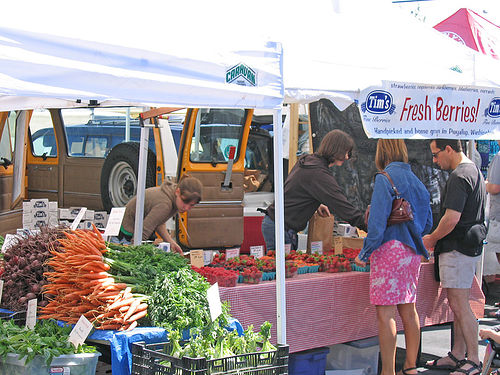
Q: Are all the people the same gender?
A: No, they are both male and female.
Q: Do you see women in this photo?
A: Yes, there is a woman.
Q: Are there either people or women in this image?
A: Yes, there is a woman.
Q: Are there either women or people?
A: Yes, there is a woman.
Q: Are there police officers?
A: No, there are no police officers.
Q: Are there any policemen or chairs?
A: No, there are no policemen or chairs.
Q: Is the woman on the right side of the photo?
A: Yes, the woman is on the right of the image.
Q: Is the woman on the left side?
A: No, the woman is on the right of the image.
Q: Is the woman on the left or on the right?
A: The woman is on the right of the image.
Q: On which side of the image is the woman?
A: The woman is on the right of the image.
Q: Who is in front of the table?
A: The woman is in front of the table.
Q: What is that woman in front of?
A: The woman is in front of the table.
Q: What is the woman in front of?
A: The woman is in front of the table.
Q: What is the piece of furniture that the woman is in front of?
A: The piece of furniture is a table.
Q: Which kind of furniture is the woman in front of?
A: The woman is in front of the table.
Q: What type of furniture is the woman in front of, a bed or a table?
A: The woman is in front of a table.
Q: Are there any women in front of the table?
A: Yes, there is a woman in front of the table.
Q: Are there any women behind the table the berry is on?
A: No, the woman is in front of the table.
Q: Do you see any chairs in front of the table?
A: No, there is a woman in front of the table.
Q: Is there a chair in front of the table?
A: No, there is a woman in front of the table.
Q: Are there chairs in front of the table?
A: No, there is a woman in front of the table.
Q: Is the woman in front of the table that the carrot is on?
A: Yes, the woman is in front of the table.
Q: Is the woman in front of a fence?
A: No, the woman is in front of the table.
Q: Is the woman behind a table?
A: No, the woman is in front of a table.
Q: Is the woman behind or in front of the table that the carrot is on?
A: The woman is in front of the table.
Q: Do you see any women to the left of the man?
A: Yes, there is a woman to the left of the man.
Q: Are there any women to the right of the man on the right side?
A: No, the woman is to the left of the man.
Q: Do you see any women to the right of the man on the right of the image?
A: No, the woman is to the left of the man.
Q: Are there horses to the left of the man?
A: No, there is a woman to the left of the man.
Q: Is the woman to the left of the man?
A: Yes, the woman is to the left of the man.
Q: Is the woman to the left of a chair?
A: No, the woman is to the left of the man.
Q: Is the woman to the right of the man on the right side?
A: No, the woman is to the left of the man.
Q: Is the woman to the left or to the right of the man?
A: The woman is to the left of the man.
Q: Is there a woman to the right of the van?
A: Yes, there is a woman to the right of the van.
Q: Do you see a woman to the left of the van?
A: No, the woman is to the right of the van.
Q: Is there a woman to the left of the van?
A: No, the woman is to the right of the van.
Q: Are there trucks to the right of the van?
A: No, there is a woman to the right of the van.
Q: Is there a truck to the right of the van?
A: No, there is a woman to the right of the van.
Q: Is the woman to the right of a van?
A: Yes, the woman is to the right of a van.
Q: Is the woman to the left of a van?
A: No, the woman is to the right of a van.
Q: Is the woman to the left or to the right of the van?
A: The woman is to the right of the van.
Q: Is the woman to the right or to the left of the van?
A: The woman is to the right of the van.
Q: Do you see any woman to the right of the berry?
A: Yes, there is a woman to the right of the berry.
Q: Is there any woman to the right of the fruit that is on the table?
A: Yes, there is a woman to the right of the berry.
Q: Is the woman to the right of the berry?
A: Yes, the woman is to the right of the berry.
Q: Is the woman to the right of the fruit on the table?
A: Yes, the woman is to the right of the berry.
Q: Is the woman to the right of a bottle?
A: No, the woman is to the right of the berry.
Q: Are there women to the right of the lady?
A: Yes, there is a woman to the right of the lady.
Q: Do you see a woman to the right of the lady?
A: Yes, there is a woman to the right of the lady.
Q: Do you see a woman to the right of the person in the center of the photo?
A: Yes, there is a woman to the right of the lady.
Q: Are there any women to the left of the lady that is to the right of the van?
A: No, the woman is to the right of the lady.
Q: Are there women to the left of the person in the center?
A: No, the woman is to the right of the lady.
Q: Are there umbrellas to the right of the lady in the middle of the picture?
A: No, there is a woman to the right of the lady.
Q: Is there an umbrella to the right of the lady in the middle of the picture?
A: No, there is a woman to the right of the lady.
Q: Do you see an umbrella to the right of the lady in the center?
A: No, there is a woman to the right of the lady.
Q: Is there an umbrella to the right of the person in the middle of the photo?
A: No, there is a woman to the right of the lady.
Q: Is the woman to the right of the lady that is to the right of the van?
A: Yes, the woman is to the right of the lady.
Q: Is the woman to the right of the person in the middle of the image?
A: Yes, the woman is to the right of the lady.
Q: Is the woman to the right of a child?
A: No, the woman is to the right of the lady.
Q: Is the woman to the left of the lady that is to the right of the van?
A: No, the woman is to the right of the lady.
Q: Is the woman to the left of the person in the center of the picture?
A: No, the woman is to the right of the lady.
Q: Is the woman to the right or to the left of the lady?
A: The woman is to the right of the lady.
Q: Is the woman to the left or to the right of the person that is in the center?
A: The woman is to the right of the lady.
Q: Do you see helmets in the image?
A: No, there are no helmets.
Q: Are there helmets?
A: No, there are no helmets.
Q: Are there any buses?
A: No, there are no buses.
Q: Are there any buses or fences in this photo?
A: No, there are no buses or fences.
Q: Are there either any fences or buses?
A: No, there are no buses or fences.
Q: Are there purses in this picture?
A: Yes, there is a purse.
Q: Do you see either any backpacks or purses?
A: Yes, there is a purse.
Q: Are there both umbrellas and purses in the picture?
A: No, there is a purse but no umbrellas.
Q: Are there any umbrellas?
A: No, there are no umbrellas.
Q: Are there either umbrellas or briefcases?
A: No, there are no umbrellas or briefcases.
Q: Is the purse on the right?
A: Yes, the purse is on the right of the image.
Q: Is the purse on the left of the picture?
A: No, the purse is on the right of the image.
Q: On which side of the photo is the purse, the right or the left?
A: The purse is on the right of the image.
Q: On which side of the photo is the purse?
A: The purse is on the right of the image.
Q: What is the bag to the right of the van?
A: The bag is a purse.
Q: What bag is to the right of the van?
A: The bag is a purse.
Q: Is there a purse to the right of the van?
A: Yes, there is a purse to the right of the van.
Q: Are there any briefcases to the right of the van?
A: No, there is a purse to the right of the van.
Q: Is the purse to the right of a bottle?
A: No, the purse is to the right of the van.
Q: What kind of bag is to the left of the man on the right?
A: The bag is a purse.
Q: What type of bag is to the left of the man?
A: The bag is a purse.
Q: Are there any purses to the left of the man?
A: Yes, there is a purse to the left of the man.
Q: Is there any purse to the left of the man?
A: Yes, there is a purse to the left of the man.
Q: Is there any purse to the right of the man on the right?
A: No, the purse is to the left of the man.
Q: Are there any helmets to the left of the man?
A: No, there is a purse to the left of the man.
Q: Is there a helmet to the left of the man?
A: No, there is a purse to the left of the man.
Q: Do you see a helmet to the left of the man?
A: No, there is a purse to the left of the man.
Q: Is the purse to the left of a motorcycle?
A: No, the purse is to the left of the man.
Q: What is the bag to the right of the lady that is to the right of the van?
A: The bag is a purse.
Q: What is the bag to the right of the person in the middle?
A: The bag is a purse.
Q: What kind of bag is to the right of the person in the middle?
A: The bag is a purse.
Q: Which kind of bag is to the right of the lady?
A: The bag is a purse.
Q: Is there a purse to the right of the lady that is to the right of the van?
A: Yes, there is a purse to the right of the lady.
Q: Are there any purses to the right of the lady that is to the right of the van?
A: Yes, there is a purse to the right of the lady.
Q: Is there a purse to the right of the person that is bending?
A: Yes, there is a purse to the right of the lady.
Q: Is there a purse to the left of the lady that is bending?
A: No, the purse is to the right of the lady.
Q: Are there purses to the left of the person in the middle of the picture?
A: No, the purse is to the right of the lady.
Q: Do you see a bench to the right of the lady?
A: No, there is a purse to the right of the lady.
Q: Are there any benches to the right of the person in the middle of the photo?
A: No, there is a purse to the right of the lady.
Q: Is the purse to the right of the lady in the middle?
A: Yes, the purse is to the right of the lady.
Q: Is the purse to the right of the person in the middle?
A: Yes, the purse is to the right of the lady.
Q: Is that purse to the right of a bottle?
A: No, the purse is to the right of the lady.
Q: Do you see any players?
A: No, there are no players.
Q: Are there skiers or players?
A: No, there are no players or skiers.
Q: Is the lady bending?
A: Yes, the lady is bending.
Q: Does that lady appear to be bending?
A: Yes, the lady is bending.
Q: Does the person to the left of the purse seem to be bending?
A: Yes, the lady is bending.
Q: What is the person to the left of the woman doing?
A: The lady is bending.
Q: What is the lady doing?
A: The lady is bending.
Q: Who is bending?
A: The lady is bending.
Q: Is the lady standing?
A: No, the lady is bending.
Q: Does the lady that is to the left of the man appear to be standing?
A: No, the lady is bending.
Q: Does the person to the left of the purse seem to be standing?
A: No, the lady is bending.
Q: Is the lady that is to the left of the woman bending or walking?
A: The lady is bending.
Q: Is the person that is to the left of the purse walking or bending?
A: The lady is bending.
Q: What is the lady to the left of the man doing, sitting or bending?
A: The lady is bending.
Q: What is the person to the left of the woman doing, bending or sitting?
A: The lady is bending.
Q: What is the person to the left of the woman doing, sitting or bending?
A: The lady is bending.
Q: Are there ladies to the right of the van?
A: Yes, there is a lady to the right of the van.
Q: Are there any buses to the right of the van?
A: No, there is a lady to the right of the van.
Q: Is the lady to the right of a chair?
A: No, the lady is to the right of the van.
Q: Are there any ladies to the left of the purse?
A: Yes, there is a lady to the left of the purse.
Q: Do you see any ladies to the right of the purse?
A: No, the lady is to the left of the purse.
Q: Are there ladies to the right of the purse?
A: No, the lady is to the left of the purse.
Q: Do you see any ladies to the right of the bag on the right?
A: No, the lady is to the left of the purse.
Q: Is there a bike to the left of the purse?
A: No, there is a lady to the left of the purse.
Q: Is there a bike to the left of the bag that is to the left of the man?
A: No, there is a lady to the left of the purse.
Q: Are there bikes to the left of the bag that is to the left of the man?
A: No, there is a lady to the left of the purse.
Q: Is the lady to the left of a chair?
A: No, the lady is to the left of the purse.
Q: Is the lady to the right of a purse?
A: No, the lady is to the left of a purse.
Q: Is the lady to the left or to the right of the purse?
A: The lady is to the left of the purse.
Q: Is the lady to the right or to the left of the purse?
A: The lady is to the left of the purse.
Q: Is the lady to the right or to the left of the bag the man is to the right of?
A: The lady is to the left of the purse.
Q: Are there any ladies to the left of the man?
A: Yes, there is a lady to the left of the man.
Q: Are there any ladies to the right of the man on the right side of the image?
A: No, the lady is to the left of the man.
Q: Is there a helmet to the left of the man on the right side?
A: No, there is a lady to the left of the man.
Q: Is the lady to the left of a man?
A: Yes, the lady is to the left of a man.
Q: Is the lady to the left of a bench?
A: No, the lady is to the left of a man.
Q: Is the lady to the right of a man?
A: No, the lady is to the left of a man.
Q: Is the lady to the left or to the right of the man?
A: The lady is to the left of the man.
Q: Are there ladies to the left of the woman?
A: Yes, there is a lady to the left of the woman.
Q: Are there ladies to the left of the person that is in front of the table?
A: Yes, there is a lady to the left of the woman.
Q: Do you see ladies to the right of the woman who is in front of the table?
A: No, the lady is to the left of the woman.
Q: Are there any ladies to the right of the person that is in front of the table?
A: No, the lady is to the left of the woman.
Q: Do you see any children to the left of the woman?
A: No, there is a lady to the left of the woman.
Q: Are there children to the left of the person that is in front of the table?
A: No, there is a lady to the left of the woman.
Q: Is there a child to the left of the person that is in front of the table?
A: No, there is a lady to the left of the woman.